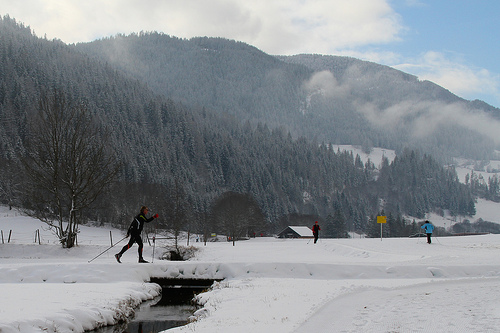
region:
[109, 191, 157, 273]
a man out on a lake.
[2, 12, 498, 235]
a tree covered mountain.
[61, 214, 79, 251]
a frozen river on snow.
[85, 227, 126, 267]
a long ski pole.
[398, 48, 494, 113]
a large white cloud.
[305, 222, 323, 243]
a man in the snow.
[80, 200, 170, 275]
a man with two poles.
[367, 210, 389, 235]
a yellow sign.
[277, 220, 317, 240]
a small cottage.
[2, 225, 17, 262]
a fence post.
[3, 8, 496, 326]
winter scene outdoor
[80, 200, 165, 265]
a person walking with ski poles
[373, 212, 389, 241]
a yellow post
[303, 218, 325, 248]
a person walking with ski poles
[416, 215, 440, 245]
a person wearing blue coat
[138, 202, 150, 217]
the head of a person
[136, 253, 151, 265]
a black shoe on the person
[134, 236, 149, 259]
the leg of a person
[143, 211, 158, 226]
the arm of a person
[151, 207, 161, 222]
a red glove on the person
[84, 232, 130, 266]
a long ski pole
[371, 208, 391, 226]
a yellow sign on the post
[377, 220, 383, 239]
a gray sign post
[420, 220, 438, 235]
a blue coat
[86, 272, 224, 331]
a small creek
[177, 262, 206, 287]
edge of a bridge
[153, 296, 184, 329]
part of a river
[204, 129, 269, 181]
part of some trees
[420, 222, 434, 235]
part of a jacket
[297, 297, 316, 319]
part of a line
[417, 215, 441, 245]
a person in a blue jacket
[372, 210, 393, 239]
a yellow sign on a post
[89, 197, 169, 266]
a person with two ski poles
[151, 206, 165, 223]
a red glove on a hand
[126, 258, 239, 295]
a bridge over a creek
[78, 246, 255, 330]
a creek running through the snow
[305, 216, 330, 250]
a person standing in the snow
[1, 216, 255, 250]
a fence running through the snow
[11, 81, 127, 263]
a bare leafless tree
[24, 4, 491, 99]
a cloudy blue sky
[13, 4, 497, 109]
sky with some clouds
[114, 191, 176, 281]
person in black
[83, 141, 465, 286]
some skiers in field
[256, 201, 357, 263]
building in background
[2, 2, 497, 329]
outside scene with people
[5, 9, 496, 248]
trees in the snow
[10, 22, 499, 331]
a snowy outside scene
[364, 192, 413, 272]
a yellow sign on a pole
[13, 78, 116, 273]
A tree with no leaves